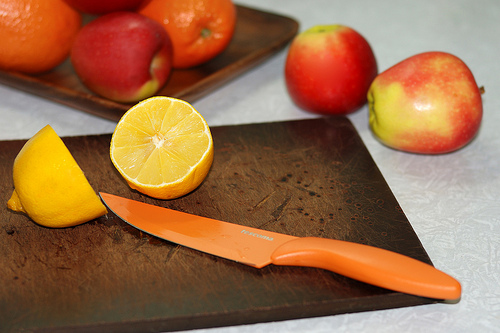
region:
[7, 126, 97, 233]
half of a yellow lemon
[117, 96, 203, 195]
half of a yellow lemon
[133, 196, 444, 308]
orange knife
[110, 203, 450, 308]
orange knife on brown wooden cutting board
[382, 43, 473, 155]
whole red and yellow apple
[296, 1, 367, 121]
whole red and yellow apple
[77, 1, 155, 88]
whole red and yellow apple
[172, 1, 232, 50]
orange on wooden cutting board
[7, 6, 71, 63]
orange on wooden cutting board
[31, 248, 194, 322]
brown wooden cutting board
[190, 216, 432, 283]
the knife is orange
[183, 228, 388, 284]
the knife is plastic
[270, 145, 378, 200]
the cutting board is made of wood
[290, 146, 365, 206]
the cutting board is brown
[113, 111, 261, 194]
the orange is cut in half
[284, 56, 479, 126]
the apples are on the table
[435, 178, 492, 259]
the counter is white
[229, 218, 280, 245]
writting is on the knife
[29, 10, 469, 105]
five fruits are on the table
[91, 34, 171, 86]
the apple is red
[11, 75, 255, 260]
a lemon cut in half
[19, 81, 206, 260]
a yellow lemon on cutting board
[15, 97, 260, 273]
a lemon on a cutting board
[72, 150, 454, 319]
an orange knife on board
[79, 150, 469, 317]
an orange knife on cutting board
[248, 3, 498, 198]
two apples on table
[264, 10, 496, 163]
two red apples on table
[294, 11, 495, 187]
two red apples next to each other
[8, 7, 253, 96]
orange and apples on plate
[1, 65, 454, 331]
lemon on plate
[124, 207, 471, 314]
an orange knife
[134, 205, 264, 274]
an orange knife blade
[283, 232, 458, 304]
an orange handle on a knife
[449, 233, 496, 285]
a white and gray table top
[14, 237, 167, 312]
a brown wood cutting board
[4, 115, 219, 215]
a sliced lemon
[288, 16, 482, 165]
two red and yellow apples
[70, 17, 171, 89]
a red apple on its side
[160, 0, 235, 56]
the end of an orange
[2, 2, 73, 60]
the rippled side of an orange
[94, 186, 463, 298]
Knife on a cutting board.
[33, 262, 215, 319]
Cutting board is wooden.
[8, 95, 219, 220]
Lemon has been cut in half.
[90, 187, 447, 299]
The knife is orange.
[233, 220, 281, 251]
The writing is white.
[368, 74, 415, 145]
Yellow on the apple.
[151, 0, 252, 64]
Orange on a tray.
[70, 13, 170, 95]
Apple on a tray.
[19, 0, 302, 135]
The tray is brown.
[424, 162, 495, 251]
The counter is blue.